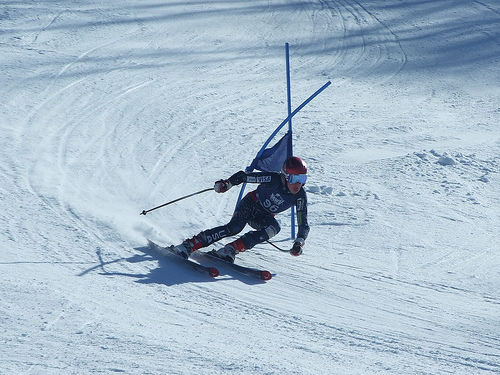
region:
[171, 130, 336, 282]
ATHLETIC PERSON ON SKI SLOPE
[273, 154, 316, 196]
HEAD OF ATHLETIC PERSON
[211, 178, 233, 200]
HAND OF ATHLETIC SKIER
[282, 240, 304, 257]
HAND OF ATHLETIC SKIER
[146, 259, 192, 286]
PART OF ATHLETIC SKIER'S SHADOW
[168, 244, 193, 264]
FOOT OF ATHLETIC SKIER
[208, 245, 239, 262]
FOOT OF ATHLETIC SKIER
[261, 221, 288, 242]
KNEE OF ATHLETIC SKIER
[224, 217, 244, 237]
KNEE OF ATHLETIC SKIER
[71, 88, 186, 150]
SKI TRACKS IN COLD SNOW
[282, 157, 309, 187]
a red helmet with white goggles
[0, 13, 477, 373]
the ski trail is curvy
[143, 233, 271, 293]
red and white skis, bindingd and boots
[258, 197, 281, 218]
the number 36 on skier's chest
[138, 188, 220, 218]
right hand holds a ski pole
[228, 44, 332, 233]
a trail marker in an X pattern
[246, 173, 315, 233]
white letters on a black top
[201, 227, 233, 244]
ski pants say this skier skis for the USA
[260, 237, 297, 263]
pole is bent in skiers left hand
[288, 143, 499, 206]
Clumps of snow off the track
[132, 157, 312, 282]
sport shown is skiing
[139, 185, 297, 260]
person is holding ski poles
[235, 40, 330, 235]
racer has just hit banner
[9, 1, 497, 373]
snow has many tracks in it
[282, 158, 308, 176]
person is wearing helmet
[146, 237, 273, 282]
skis are red and white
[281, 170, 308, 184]
racer is wearing ski goggles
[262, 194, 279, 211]
number 96 on racers torso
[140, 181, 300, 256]
ski poles are black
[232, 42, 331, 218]
banner is bent from racer ski pole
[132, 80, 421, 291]
person on the snow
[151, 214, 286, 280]
skis on person's feet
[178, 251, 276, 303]
front of the skis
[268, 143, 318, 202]
head of the person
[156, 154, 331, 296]
person wearing a ski outfit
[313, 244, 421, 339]
snow on the ground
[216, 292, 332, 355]
tracks in the snow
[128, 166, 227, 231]
ski pole in person's hand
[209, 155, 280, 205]
arm of the person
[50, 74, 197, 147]
snow behind the skier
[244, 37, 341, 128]
two poles to flags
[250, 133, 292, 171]
blue flags on pole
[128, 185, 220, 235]
black ski pole in hand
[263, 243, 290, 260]
black ski pole in hand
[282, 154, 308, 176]
red helmet on head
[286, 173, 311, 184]
silver goggles on face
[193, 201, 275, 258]
black ski pants on man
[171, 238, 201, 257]
black and red ski shoes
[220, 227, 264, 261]
black and red ski shoes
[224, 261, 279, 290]
black and red skis